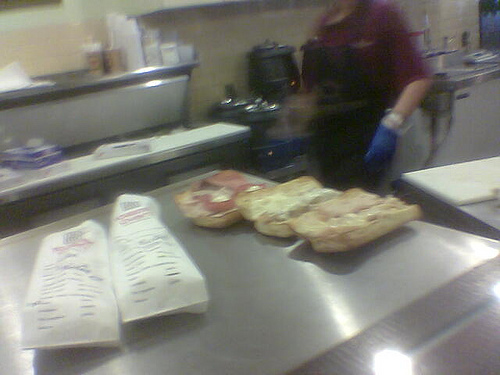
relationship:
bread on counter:
[288, 186, 425, 252] [10, 160, 498, 373]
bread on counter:
[234, 175, 344, 238] [10, 160, 498, 373]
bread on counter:
[175, 168, 268, 228] [10, 160, 498, 373]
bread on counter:
[288, 186, 425, 252] [208, 248, 464, 341]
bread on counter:
[234, 175, 344, 238] [208, 248, 464, 341]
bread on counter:
[175, 168, 268, 228] [208, 248, 464, 341]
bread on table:
[288, 186, 425, 252] [214, 257, 488, 316]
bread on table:
[234, 175, 344, 238] [214, 257, 488, 316]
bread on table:
[175, 168, 268, 228] [214, 257, 488, 316]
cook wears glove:
[263, 7, 434, 211] [361, 117, 408, 171]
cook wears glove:
[263, 7, 434, 211] [248, 125, 312, 173]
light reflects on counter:
[370, 342, 416, 374] [10, 160, 498, 373]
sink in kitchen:
[425, 46, 500, 83] [10, 9, 498, 369]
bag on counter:
[28, 183, 275, 343] [10, 160, 498, 373]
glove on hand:
[364, 124, 406, 171] [369, 127, 408, 170]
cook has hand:
[277, 0, 435, 195] [369, 127, 408, 170]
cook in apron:
[277, 0, 435, 195] [305, 33, 390, 193]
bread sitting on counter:
[175, 168, 268, 228] [0, 169, 499, 374]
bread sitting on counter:
[234, 175, 344, 238] [0, 169, 499, 374]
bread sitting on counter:
[288, 186, 425, 252] [0, 169, 499, 374]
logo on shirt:
[351, 33, 376, 49] [297, 41, 363, 135]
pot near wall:
[246, 41, 302, 96] [151, 4, 485, 114]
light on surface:
[370, 342, 416, 374] [1, 168, 497, 373]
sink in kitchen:
[431, 42, 483, 83] [10, 9, 498, 369]